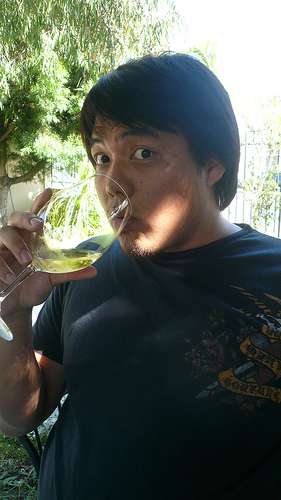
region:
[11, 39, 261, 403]
asian man drinking wine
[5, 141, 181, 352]
a glass of white wine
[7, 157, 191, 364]
white wine in wine glass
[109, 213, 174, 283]
a scruff of beard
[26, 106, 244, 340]
man making surprised face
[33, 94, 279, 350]
his hair is black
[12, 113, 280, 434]
the shirt is black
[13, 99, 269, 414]
the man is holding a glass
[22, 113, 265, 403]
the person is male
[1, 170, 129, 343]
large wine glass with white wine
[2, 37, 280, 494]
man holding wine glass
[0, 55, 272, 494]
man drinking from wine glass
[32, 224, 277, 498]
black shirt with colorful design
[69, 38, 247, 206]
man has straight black hair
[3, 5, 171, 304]
large green tree behind man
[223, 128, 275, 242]
metal fence behind man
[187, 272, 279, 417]
design on man's black shirt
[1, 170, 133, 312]
man's hand is holding wine glass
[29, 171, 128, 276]
wine glass has white wine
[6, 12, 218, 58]
a large tree in the background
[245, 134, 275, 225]
a fence in the yard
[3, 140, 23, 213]
the trunk of the tree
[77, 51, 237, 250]
a man drinking out of a glass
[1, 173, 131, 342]
a wine glass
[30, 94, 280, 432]
a man in a black shirt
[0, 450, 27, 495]
grass on the ground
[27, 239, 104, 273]
the drink in the glass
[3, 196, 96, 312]
the hand of the man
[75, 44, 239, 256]
a boy with dark hair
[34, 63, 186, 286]
man is drinking wine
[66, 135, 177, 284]
man is drinking wine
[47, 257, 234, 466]
the shirt is black